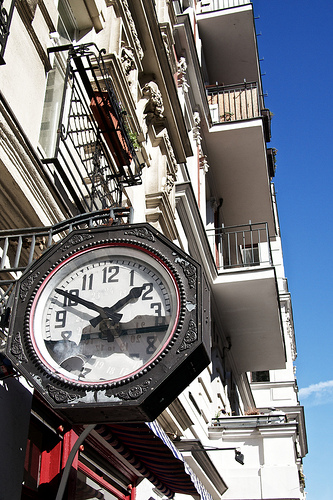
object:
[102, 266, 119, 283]
number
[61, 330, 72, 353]
number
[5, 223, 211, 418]
clock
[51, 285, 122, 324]
hand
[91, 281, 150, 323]
hand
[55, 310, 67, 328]
number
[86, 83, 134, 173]
flower box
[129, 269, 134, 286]
number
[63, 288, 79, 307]
number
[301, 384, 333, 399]
cloud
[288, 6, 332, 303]
sky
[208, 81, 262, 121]
railing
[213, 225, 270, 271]
railing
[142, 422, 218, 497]
awining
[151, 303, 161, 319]
number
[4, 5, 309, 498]
building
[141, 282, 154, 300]
number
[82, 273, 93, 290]
number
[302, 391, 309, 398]
part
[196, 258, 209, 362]
edge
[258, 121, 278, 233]
edge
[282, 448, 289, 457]
part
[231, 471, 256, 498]
wall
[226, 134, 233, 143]
part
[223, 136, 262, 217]
surface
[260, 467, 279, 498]
part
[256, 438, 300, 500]
pillar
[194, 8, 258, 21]
edge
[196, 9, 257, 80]
roof